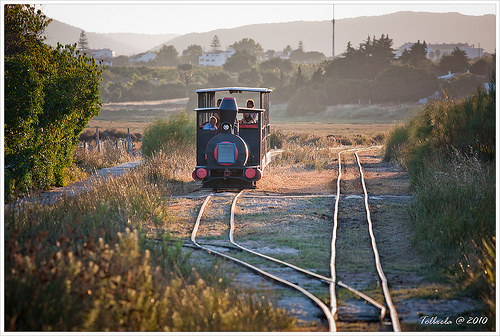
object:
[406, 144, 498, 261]
bush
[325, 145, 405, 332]
track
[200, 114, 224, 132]
man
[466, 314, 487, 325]
date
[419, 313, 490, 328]
artist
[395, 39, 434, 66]
trees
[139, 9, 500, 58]
mountains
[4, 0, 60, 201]
bush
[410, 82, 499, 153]
bush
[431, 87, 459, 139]
bush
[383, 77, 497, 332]
hill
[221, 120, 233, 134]
light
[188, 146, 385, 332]
tracks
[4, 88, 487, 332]
ground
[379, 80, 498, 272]
tree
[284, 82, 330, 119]
bush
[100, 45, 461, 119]
hill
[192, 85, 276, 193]
train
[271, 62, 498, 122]
hill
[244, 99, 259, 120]
people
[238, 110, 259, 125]
people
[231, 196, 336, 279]
grass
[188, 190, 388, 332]
tracks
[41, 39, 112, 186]
bush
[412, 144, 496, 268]
weeds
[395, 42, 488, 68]
building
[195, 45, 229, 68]
building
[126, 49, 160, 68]
building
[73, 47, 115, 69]
building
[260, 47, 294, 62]
building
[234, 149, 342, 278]
ground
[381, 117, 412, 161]
bush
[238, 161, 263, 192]
wheel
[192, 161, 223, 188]
wheel